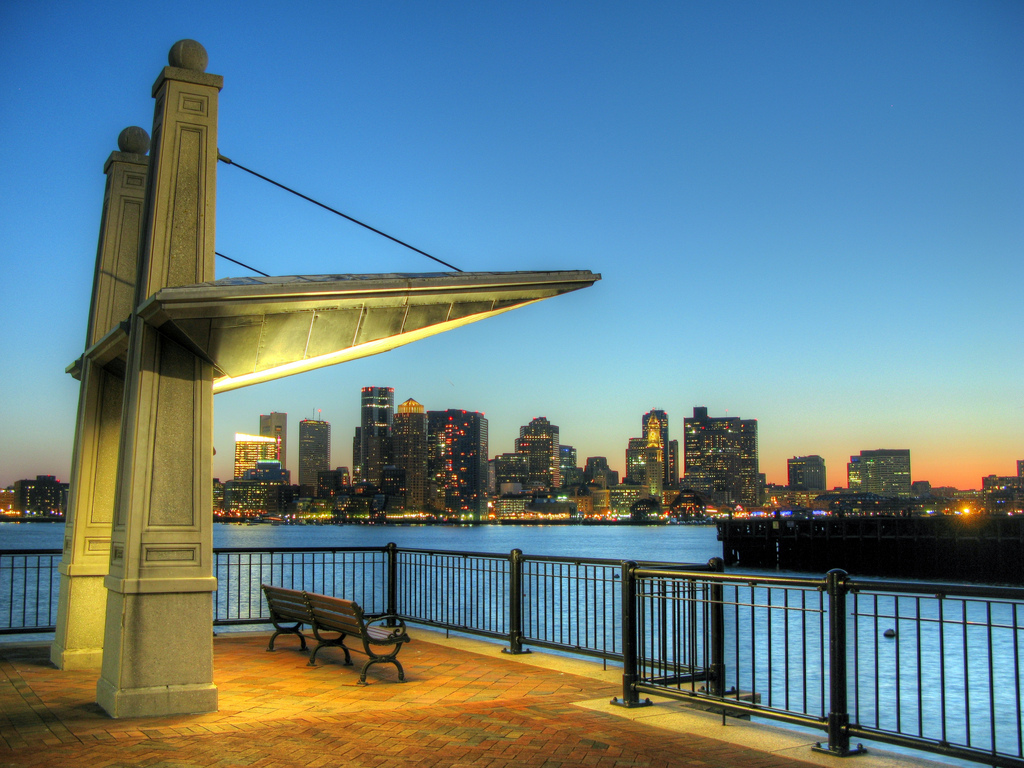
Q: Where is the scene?
A: At a water walkway.